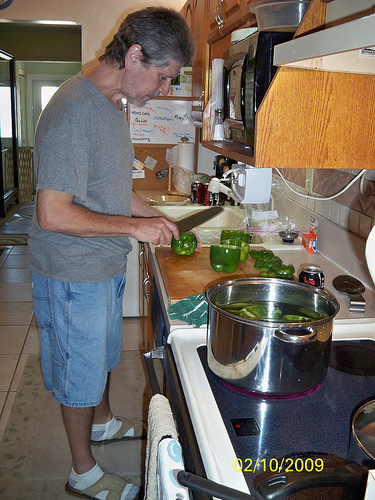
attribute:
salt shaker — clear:
[207, 106, 226, 143]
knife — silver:
[175, 196, 215, 228]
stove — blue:
[147, 321, 374, 498]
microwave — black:
[217, 30, 295, 154]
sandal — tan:
[67, 472, 135, 499]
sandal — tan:
[92, 419, 154, 442]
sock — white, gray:
[89, 414, 132, 438]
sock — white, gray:
[69, 456, 140, 497]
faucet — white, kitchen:
[204, 167, 236, 201]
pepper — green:
[169, 217, 205, 258]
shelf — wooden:
[187, 30, 354, 168]